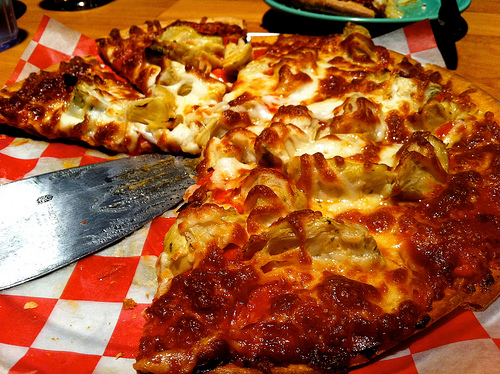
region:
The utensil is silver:
[0, 138, 196, 278]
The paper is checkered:
[10, 31, 410, 366]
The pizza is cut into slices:
[32, 30, 482, 350]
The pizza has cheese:
[35, 26, 466, 342]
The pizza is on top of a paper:
[30, 15, 472, 365]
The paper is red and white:
[22, 36, 462, 356]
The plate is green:
[243, 0, 474, 45]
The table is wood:
[23, 4, 486, 106]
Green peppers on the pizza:
[70, 36, 454, 281]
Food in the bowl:
[268, 0, 484, 43]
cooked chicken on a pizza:
[268, 190, 404, 277]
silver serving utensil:
[0, 96, 237, 333]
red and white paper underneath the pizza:
[11, 232, 144, 369]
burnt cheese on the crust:
[294, 315, 356, 372]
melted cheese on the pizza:
[293, 125, 364, 168]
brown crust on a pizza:
[433, 53, 495, 120]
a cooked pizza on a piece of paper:
[21, 16, 498, 365]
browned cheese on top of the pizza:
[162, 222, 290, 339]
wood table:
[142, 3, 219, 20]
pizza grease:
[122, 146, 202, 193]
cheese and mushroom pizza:
[35, 28, 482, 347]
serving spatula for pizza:
[2, 170, 218, 292]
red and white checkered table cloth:
[53, 252, 150, 370]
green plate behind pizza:
[250, 0, 499, 58]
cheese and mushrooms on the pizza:
[252, 75, 445, 213]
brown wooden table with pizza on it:
[37, 2, 279, 42]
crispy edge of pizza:
[205, 283, 443, 371]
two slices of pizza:
[23, 18, 258, 157]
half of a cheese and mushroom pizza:
[211, 32, 493, 367]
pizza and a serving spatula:
[30, 20, 171, 370]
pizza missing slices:
[5, 96, 218, 371]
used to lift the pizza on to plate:
[6, 144, 237, 333]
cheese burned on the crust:
[209, 311, 416, 366]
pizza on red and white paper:
[0, 139, 174, 360]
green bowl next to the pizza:
[318, 3, 472, 46]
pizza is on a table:
[90, 28, 498, 223]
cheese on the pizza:
[293, 74, 357, 171]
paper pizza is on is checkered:
[23, 274, 133, 372]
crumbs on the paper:
[12, 288, 142, 364]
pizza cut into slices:
[24, 43, 294, 153]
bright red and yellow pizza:
[46, 16, 494, 365]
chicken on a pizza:
[249, 105, 429, 280]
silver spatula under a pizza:
[0, 123, 216, 308]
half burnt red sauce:
[147, 259, 422, 370]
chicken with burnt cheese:
[401, 131, 448, 195]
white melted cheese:
[127, 44, 450, 172]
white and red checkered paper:
[7, 31, 202, 356]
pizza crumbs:
[19, 251, 151, 338]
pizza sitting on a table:
[5, 10, 493, 365]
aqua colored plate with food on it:
[262, 0, 485, 55]